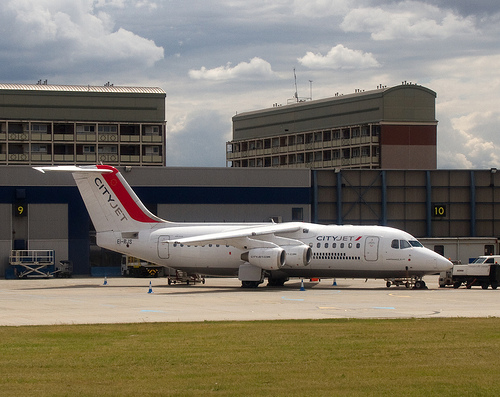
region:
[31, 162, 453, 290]
an executive jet is parked at the terminal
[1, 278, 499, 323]
the tarmac is made of asphalt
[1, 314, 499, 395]
a grassy field is next to the tarmac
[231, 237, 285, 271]
the jet engine is mounted to the wing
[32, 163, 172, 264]
the jets tail section has the logo and colors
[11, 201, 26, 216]
the terminal is marked with the number 9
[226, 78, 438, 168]
a commercial building is behind the terminal building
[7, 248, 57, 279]
a scissor lift is in front of terminal 9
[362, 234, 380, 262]
a side door to the front and cockpit of the jet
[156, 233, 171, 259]
a rear door to the tail section of the jet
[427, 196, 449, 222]
A number 10 on a building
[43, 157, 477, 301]
A small jet plane at an airport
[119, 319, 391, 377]
Grass along a taxiway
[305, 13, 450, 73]
Clouds drifting in the sky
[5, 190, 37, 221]
A number 9 on a building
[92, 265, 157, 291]
Blue safety cones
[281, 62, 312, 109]
An antenna on an airport building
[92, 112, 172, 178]
Windows in a building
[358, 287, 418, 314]
Yellow and blue markings on the concrete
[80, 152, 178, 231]
A red stripe on a plane's tale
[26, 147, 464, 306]
a small jet aircraft on the runway at the airport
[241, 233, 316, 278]
two jet engines attached to the aircraft's wing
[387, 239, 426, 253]
the windows in the cockpit of the aircraft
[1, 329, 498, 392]
green grass growing next to the runway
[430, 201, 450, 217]
a black and yellow sign indicating gate 10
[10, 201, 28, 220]
a black and yellow sign indicating gate 9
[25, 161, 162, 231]
the tail of the plane with a red stripe and the words Cityjet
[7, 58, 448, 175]
two tall buildings at the terminal part of the airport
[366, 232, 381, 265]
the front door on the aircraft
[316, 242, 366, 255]
a row of small windows on the aircraft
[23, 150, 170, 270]
the tail of a plane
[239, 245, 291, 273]
the engine of a plane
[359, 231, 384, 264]
the door of a plane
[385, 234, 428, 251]
the windshield of a plane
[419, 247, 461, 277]
the nose of a plane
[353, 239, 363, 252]
the window of a plane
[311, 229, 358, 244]
writing on a plane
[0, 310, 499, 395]
green grass on the ground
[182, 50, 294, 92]
a gray cloud in the sky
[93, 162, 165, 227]
a red stripe on the plane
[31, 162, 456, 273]
white CityJet airplane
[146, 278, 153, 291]
blue and white cone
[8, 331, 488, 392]
greenish brown grass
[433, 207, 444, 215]
black sign with a yellow number 10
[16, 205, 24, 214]
black sign with a yellow number 9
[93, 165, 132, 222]
red stripe on an airplane tail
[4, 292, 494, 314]
airport tarmac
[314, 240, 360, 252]
passenger windows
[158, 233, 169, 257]
airplane's rear exit door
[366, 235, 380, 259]
airplane's front door